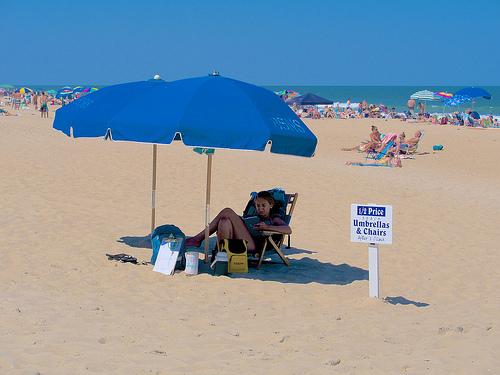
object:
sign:
[351, 204, 393, 244]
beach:
[0, 96, 498, 375]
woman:
[184, 191, 292, 248]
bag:
[220, 239, 248, 272]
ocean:
[24, 86, 499, 115]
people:
[342, 125, 381, 152]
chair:
[241, 193, 299, 270]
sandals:
[115, 255, 137, 262]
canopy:
[106, 74, 316, 157]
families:
[2, 87, 500, 130]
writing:
[353, 220, 389, 236]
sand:
[0, 106, 499, 375]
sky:
[0, 2, 498, 86]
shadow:
[224, 257, 369, 285]